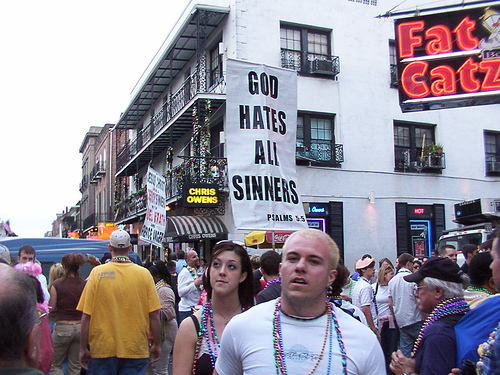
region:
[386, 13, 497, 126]
black sign with red words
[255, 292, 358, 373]
party beads around man's neck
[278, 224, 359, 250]
man's short blond hair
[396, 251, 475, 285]
blue hat with brim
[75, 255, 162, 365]
large size yellow shirt with logo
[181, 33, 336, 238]
large white banner with black wording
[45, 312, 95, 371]
brown pants with brown belt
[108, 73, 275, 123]
black railings on building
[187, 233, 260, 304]
woman with medium length black hair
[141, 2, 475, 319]
large white building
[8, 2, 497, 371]
People walking in a street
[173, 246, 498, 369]
People with necklaces of colorful beads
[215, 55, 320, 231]
White sign with black letters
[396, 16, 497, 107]
Light sign with red letters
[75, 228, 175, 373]
Man wearing a yellow T-shirt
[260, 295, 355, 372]
Bead necklaces of different colors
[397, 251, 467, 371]
Old man with gray hair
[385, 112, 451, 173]
Window of building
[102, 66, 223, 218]
Building with balconies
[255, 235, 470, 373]
Males wearing necklaces of bead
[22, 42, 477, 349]
crowded intersection in a town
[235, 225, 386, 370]
man wearing colorful strands of beads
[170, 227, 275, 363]
woman with eyes looking up toward the side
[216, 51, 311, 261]
sign held by person with religious quote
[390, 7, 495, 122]
elevated sign with orange and red lit letters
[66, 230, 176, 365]
broad shouldered person in yellow shirt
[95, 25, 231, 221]
wrought iron railings on outside terraces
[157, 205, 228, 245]
curved black and white awning for business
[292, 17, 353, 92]
window with air conditioner inside metal railing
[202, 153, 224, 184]
clown-like face on side of building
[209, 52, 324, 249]
WHITE AND BLACK SIGN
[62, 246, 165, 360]
MAN WEARING YELLOW SHIRT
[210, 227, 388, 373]
MAN WEARING WHITE SHIRT AND BEADS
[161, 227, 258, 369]
LADY WEARING BEADS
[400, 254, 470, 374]
MAN WITH CAP AND GLASSES WEARING BEADS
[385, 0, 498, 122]
FAT CATZ SIGN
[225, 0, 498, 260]
BLACK AND WHITE BUILDING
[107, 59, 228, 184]
BALCONY OF BUILDING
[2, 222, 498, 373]
CROWD OF PEOPLE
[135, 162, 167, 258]
SOMEONE HOLDING UP POSTER SIGN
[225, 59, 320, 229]
white sign with black lettering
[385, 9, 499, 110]
neon sign of a business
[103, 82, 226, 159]
balcony on a building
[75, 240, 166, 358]
man in a yellow short sleeved shirt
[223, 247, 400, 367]
man in a white teeshirt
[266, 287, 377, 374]
colorful beads around a persons neck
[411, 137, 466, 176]
air conditioner in a window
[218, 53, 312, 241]
sign of a street preacher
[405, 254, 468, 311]
man in a black ball cap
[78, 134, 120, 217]
two brick buildings